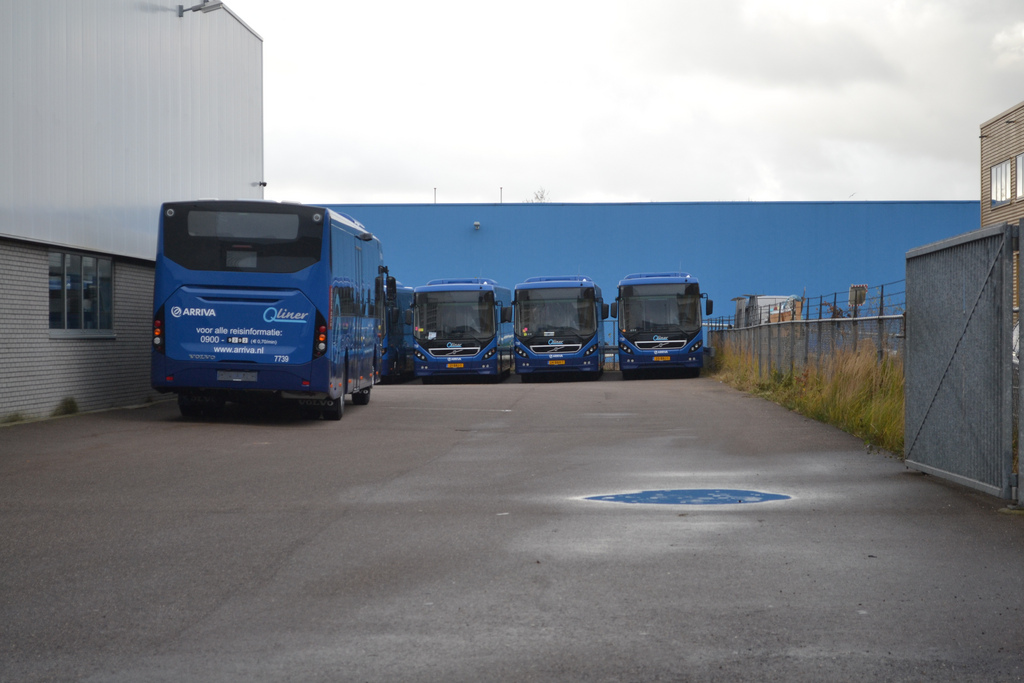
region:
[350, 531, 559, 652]
the street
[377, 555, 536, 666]
the street is grey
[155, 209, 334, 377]
a blue bus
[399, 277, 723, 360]
three buses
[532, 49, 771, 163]
clouds in the sky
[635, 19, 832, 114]
the sky is cloudy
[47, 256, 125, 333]
windows on the building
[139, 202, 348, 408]
White writing on the back of a bus.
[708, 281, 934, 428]
A gray chain link fence .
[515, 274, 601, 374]
A front end of a blue bus.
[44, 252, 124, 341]
A window on a side of brick building.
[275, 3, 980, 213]
A cloudy gray sky above the building.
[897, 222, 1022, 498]
A gray wooden gate panel.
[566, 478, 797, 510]
A puddle of water on the black top.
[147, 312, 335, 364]
Rear lights on a blue bus.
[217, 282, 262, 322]
the bus is blue in color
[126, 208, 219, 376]
the bus is parked beside the building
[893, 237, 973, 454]
the gate is opened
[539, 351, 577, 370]
the tag on the bus is orange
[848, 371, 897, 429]
the grass is light green in color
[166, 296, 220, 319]
the word is white on the bus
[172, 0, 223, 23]
the light on the building is off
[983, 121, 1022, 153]
the building is tan in color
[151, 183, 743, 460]
Buses parked in a lot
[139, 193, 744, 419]
Blue buses parked in a lot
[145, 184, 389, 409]
Bus parked in a lot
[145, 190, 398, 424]
Blue bus parked in a lot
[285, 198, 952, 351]
Blue wall behind buses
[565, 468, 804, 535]
Puddle in the parking lot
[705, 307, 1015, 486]
Fence around parking lot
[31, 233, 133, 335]
Window in the building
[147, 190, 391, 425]
Blue bus parked near window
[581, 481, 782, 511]
a puddle of water on the pavement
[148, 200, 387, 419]
a blue bus with white writing on the back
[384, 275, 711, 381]
four buses parked in a line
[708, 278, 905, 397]
a chain link fence topped with barbed wire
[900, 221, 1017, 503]
a wooden fence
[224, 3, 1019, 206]
the sky is full of white clouds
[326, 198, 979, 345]
a blue colored building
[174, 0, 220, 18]
a light attached to the building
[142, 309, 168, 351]
part on a bus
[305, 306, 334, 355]
part on a bus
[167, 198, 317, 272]
part on a bus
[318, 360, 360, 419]
part on a bus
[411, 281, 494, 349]
part on a bus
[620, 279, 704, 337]
part on a bus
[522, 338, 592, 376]
part on a bus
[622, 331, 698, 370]
part on a bus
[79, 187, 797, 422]
a set of buses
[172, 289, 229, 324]
white writing on a bus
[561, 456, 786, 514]
a puddle of water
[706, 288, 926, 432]
a fence on the side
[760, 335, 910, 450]
a patch of weeds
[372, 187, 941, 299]
a long blue wall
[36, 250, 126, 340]
a set of windows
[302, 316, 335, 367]
tail lights on the bus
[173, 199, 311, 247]
back window on the bus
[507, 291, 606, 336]
front window on the bus